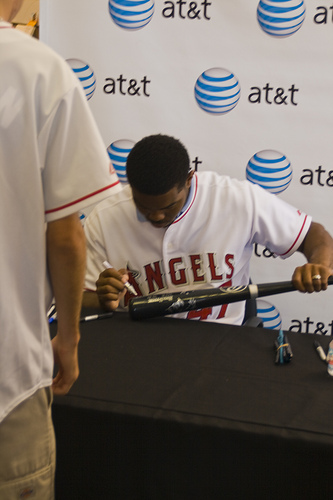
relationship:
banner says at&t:
[37, 0, 332, 338] [103, 1, 218, 34]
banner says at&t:
[37, 0, 332, 338] [191, 67, 303, 118]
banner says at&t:
[37, 0, 332, 338] [52, 58, 152, 101]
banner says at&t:
[37, 0, 332, 338] [244, 147, 332, 198]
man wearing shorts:
[1, 14, 122, 499] [5, 375, 69, 499]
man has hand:
[1, 14, 122, 499] [49, 332, 86, 398]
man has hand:
[78, 133, 332, 329] [286, 261, 332, 294]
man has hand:
[78, 133, 332, 329] [94, 263, 134, 314]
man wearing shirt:
[1, 14, 122, 499] [1, 19, 127, 427]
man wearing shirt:
[78, 133, 332, 329] [82, 170, 314, 329]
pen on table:
[310, 336, 328, 363] [48, 296, 333, 498]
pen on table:
[75, 309, 115, 324] [48, 296, 333, 498]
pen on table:
[48, 310, 62, 328] [48, 296, 333, 498]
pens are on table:
[270, 328, 297, 366] [48, 296, 333, 498]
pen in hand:
[100, 254, 141, 297] [94, 263, 134, 314]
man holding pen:
[78, 133, 332, 329] [100, 254, 141, 297]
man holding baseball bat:
[78, 133, 332, 329] [126, 269, 333, 323]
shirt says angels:
[82, 170, 314, 329] [120, 250, 240, 310]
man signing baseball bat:
[78, 133, 332, 329] [126, 269, 333, 323]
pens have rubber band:
[270, 328, 297, 366] [272, 339, 292, 355]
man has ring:
[78, 133, 332, 329] [310, 272, 324, 282]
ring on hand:
[310, 272, 324, 282] [286, 261, 332, 294]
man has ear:
[78, 133, 332, 329] [185, 166, 195, 190]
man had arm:
[1, 14, 122, 499] [43, 54, 92, 400]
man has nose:
[78, 133, 332, 329] [147, 207, 168, 225]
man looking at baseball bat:
[78, 133, 332, 329] [126, 269, 333, 323]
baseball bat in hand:
[126, 269, 333, 323] [286, 261, 332, 294]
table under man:
[48, 296, 333, 498] [78, 133, 332, 329]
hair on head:
[126, 132, 190, 191] [125, 131, 195, 230]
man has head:
[78, 133, 332, 329] [125, 131, 195, 230]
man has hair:
[78, 133, 332, 329] [126, 132, 190, 191]